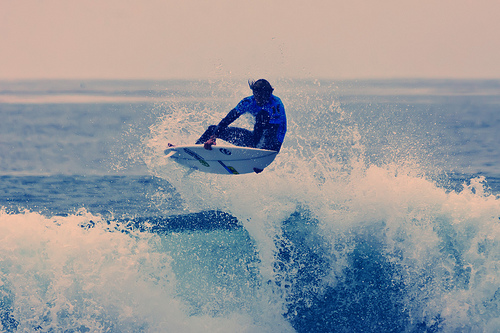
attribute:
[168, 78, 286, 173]
man — surfing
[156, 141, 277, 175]
surfboard — pointy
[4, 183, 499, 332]
wave — LARGE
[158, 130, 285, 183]
surfboard — white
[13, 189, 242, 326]
wave — foamy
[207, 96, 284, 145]
wet suit — blue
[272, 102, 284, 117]
logo — black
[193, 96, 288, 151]
wet suit — blue and black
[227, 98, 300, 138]
top — blue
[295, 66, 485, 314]
wave — large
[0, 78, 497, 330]
water — blue